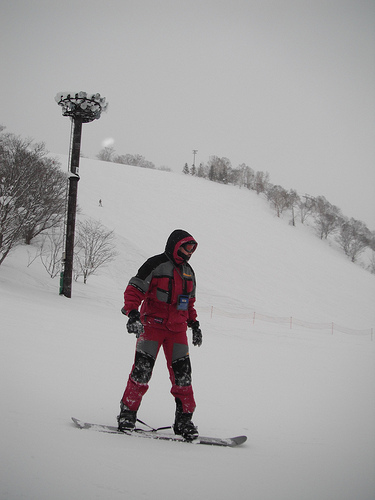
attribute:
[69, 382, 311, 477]
skiboard — gray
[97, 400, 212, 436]
boots — black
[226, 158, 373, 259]
trees — small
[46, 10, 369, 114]
sky — gray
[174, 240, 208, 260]
goggles — protective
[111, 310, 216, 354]
gloves — black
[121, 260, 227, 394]
suit — red, black